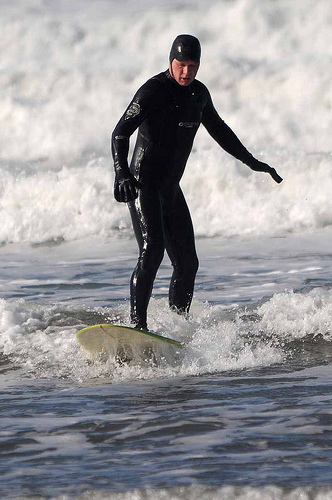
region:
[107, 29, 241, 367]
the man is surfing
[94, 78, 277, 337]
a black wet suit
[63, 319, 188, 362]
a green surf board in the water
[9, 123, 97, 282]
ocean waves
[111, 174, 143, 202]
black hand gloves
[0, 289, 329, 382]
surfing on waves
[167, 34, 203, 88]
a man in a black hat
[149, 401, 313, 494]
blue ocean water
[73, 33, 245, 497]
the man is surfing in the water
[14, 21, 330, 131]
waves in the background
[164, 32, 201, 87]
the head of a man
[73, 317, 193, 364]
a green and white surfboard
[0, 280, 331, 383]
white foaming water around the surfboard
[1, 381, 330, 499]
calm blue water in front of the surfboard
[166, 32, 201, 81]
a black helmet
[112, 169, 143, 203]
a black glove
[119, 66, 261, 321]
a black wet suit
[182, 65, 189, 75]
the nose of a man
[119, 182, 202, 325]
the legs of a man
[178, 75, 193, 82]
the mouth of a man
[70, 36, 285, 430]
a man surfing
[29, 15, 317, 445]
a man surfs in the ocean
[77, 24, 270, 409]
a man standing on a surf board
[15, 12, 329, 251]
waves coming into shore in the ocean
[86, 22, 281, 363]
a man in black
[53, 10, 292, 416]
the surfer wears a black wet suit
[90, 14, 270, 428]
the man's wet suit has a hood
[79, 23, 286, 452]
a man watches the water at his feet as he surfs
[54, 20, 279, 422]
a man balances on a surf board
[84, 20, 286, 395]
the surfer wears a whole body wet suit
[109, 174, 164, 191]
black gloves on man's hand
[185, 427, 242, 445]
calm white waves in the water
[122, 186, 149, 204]
fingers on the glove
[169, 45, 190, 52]
white label on cap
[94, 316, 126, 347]
small line at bottom of surf board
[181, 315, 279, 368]
large section of white waves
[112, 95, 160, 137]
symbol on wet suit arm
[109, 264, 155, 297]
shine on wet suit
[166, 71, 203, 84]
pink lips on man's face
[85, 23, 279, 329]
man standing on surfboard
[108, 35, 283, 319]
a man in a wet suit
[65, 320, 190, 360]
man is on the surfboard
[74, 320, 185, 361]
surfboard is in the water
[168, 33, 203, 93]
man wearing bathing cap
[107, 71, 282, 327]
wet suit is black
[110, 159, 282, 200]
the wet suit has gloves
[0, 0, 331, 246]
waves behind the man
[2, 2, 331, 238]
waves are foamy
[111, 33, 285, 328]
man surfing is older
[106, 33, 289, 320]
the man on the surfboard is wet